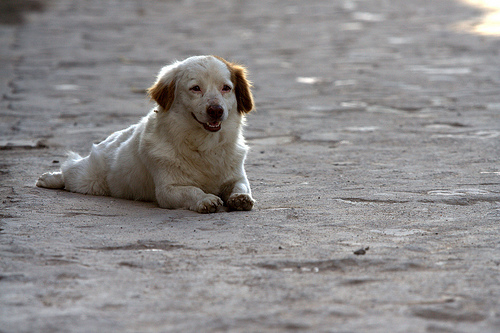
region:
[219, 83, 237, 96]
Eye of furry pup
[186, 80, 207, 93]
Eye of furry put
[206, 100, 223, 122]
Nose of furry pup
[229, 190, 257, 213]
Paw of furry pup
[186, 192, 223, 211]
Paw of furry pup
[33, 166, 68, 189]
Back paw of furry pup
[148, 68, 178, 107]
Ear of furry pup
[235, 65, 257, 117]
Ear of furry pup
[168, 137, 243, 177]
Furry chest of pup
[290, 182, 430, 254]
Dirt ground with uneven areas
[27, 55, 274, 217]
dog lying on the ground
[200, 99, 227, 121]
black nose of a dog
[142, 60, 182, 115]
ear of a dog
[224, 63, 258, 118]
ear of a dog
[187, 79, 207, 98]
eye of a dog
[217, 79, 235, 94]
eye of a dog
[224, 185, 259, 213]
paw of a dog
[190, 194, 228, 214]
paw of a dog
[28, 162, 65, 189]
hind leg of a dog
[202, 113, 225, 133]
mouth of a dog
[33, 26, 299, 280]
the dog is laying down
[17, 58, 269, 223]
the dog is white with a little brown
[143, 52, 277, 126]
his ears are brown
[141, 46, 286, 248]
the dog appears to be happy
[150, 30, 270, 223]
the dog appears to be smiling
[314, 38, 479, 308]
it appears to be sandy ground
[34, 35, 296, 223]
the dog seems to be content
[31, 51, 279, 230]
the dog is lying with his back legs stretched out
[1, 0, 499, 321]
the dog is the subject of the photo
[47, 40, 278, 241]
the dog looks a little dirty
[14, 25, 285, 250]
the dog is sitting on the ground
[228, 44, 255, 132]
the dog's ear is brown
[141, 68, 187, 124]
the dog's ear is brown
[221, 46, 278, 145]
the dog's ear is brown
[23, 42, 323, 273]
dog laying on the ground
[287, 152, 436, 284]
ground is made of sand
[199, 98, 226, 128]
dog has black nose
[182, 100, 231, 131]
dog has mouth open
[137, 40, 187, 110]
dog has brown ears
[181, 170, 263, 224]
dog has some claws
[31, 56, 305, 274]
dog has legs on ground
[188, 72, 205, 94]
dog has black eyes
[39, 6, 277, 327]
dog is light brown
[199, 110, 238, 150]
teeth showing on dog